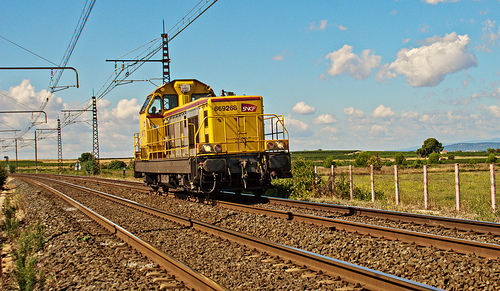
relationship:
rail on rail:
[20, 170, 500, 286] [20, 170, 500, 286]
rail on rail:
[20, 170, 226, 285] [20, 170, 500, 286]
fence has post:
[305, 155, 484, 213] [450, 154, 467, 212]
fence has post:
[305, 155, 484, 213] [451, 160, 466, 213]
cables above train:
[3, 0, 225, 158] [130, 73, 293, 203]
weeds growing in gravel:
[3, 203, 59, 287] [0, 173, 175, 288]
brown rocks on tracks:
[29, 180, 500, 291] [12, 172, 498, 287]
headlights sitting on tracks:
[132, 79, 294, 196] [12, 172, 498, 287]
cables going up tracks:
[3, 0, 225, 158] [113, 200, 414, 265]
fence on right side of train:
[298, 155, 500, 213] [134, 78, 291, 208]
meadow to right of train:
[317, 162, 499, 213] [130, 73, 293, 203]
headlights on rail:
[132, 79, 294, 196] [20, 170, 500, 286]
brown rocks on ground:
[29, 180, 500, 291] [19, 168, 489, 289]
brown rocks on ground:
[29, 180, 500, 291] [0, 152, 499, 288]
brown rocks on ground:
[29, 180, 500, 291] [11, 160, 492, 285]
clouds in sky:
[392, 30, 479, 85] [289, 8, 499, 105]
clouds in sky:
[324, 42, 382, 80] [289, 8, 499, 105]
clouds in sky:
[292, 100, 316, 115] [289, 8, 499, 105]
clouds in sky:
[312, 112, 342, 124] [289, 8, 499, 105]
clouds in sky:
[308, 16, 328, 30] [289, 8, 499, 105]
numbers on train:
[212, 104, 234, 112] [134, 78, 291, 208]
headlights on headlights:
[203, 142, 212, 154] [132, 79, 294, 196]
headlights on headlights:
[131, 80, 294, 195] [132, 79, 294, 196]